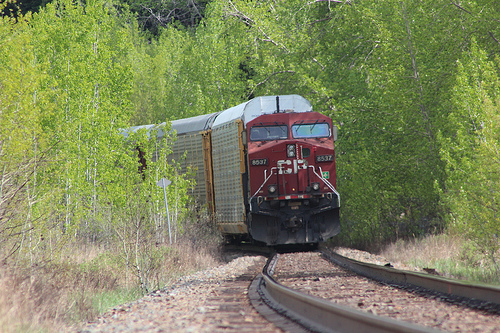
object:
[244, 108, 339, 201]
paint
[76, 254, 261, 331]
pebbles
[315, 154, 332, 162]
number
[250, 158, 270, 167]
numbers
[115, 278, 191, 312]
stones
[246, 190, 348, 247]
metal plate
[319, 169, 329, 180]
green symbol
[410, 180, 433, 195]
ground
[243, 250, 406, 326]
green vegetables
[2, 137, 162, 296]
bushes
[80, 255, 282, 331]
rocks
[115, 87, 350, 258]
train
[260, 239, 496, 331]
tracks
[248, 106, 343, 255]
front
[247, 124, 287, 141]
window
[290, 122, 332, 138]
window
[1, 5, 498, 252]
trees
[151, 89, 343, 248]
cars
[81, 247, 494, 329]
ground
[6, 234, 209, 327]
grass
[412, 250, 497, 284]
grass